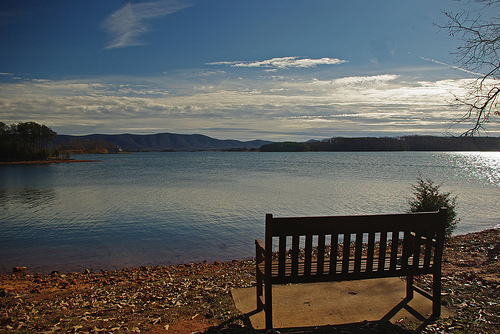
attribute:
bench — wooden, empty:
[234, 201, 457, 333]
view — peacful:
[2, 73, 498, 277]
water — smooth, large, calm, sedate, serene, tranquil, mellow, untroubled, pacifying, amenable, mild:
[1, 145, 495, 308]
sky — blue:
[6, 1, 496, 148]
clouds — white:
[3, 7, 497, 147]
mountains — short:
[0, 114, 499, 159]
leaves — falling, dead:
[9, 257, 497, 331]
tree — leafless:
[429, 2, 500, 153]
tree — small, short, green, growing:
[401, 168, 467, 242]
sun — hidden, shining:
[419, 64, 492, 123]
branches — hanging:
[442, 80, 500, 147]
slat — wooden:
[276, 234, 291, 279]